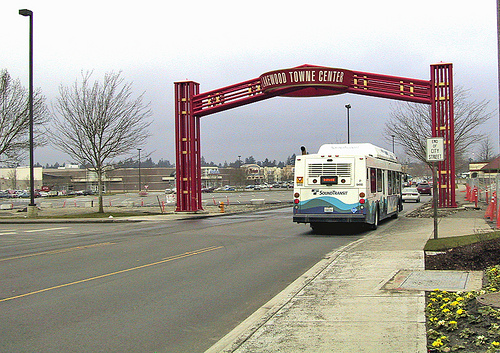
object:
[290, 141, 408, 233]
bus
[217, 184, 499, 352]
sidewalk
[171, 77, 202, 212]
metal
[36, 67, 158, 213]
tree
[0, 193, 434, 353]
road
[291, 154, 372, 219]
back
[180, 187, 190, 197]
decaorations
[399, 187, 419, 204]
car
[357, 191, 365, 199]
blinkers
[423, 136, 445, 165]
sign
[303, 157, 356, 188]
engine door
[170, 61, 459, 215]
archway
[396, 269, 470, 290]
electrical entryway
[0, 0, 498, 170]
sky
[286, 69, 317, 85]
towne(town)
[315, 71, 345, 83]
center(city)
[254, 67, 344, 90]
logo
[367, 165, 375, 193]
window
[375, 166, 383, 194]
window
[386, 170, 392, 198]
window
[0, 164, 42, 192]
building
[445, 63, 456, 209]
red bars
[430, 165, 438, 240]
pole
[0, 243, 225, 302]
yellow line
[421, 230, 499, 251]
grass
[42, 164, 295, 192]
shopping center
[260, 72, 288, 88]
words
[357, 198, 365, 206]
tail light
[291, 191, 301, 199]
tail light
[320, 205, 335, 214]
license plate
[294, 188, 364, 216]
artwork